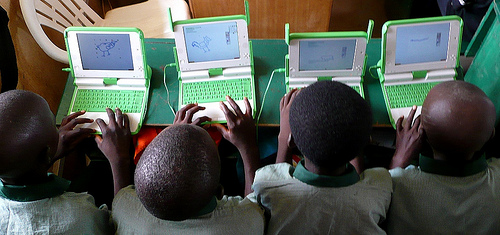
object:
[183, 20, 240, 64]
screen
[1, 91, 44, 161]
hair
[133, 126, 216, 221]
hair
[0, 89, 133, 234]
boy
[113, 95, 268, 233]
boy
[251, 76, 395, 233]
boy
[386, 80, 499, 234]
boy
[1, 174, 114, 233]
shirt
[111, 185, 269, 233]
shirt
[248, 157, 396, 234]
shirt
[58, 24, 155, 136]
laptop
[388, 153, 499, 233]
shirt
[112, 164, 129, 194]
arm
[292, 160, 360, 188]
collar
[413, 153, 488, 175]
collar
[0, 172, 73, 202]
collar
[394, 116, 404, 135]
fingers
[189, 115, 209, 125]
fingers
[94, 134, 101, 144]
fingers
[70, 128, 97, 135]
fingers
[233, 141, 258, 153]
wrist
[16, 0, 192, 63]
chair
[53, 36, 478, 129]
table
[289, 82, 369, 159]
hair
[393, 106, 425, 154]
hand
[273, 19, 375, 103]
laptops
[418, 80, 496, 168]
head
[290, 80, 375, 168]
head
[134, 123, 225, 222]
head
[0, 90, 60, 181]
head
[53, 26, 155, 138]
computer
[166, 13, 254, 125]
laptop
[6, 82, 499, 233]
row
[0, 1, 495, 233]
photo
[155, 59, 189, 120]
hookup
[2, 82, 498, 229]
children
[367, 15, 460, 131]
laptops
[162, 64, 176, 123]
cord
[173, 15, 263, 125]
computers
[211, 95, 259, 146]
hand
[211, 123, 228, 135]
finger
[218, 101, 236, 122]
finger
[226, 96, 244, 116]
finger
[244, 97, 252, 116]
finger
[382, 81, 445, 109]
keyboard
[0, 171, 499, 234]
bench